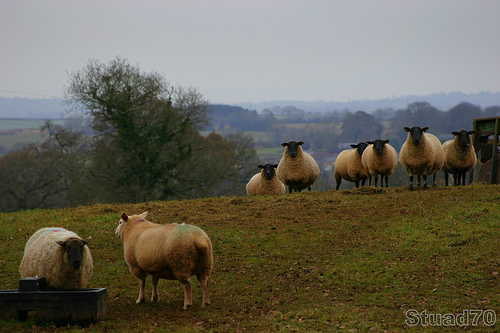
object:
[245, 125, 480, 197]
herd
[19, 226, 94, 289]
sheep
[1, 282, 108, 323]
water trough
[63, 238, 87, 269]
face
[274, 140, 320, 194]
sheep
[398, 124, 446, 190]
sheep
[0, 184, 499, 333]
hill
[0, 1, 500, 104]
sky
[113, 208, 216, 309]
sheep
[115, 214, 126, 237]
face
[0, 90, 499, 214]
valley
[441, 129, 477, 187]
sheep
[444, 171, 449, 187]
leg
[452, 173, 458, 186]
leg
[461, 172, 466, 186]
leg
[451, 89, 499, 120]
mountains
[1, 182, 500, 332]
grass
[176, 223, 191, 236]
mark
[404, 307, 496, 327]
text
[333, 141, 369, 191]
sheep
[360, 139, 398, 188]
sheep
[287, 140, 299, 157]
face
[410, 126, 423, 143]
face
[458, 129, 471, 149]
face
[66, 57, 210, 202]
tree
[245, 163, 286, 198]
sheep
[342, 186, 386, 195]
mound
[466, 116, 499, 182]
sign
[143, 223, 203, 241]
back